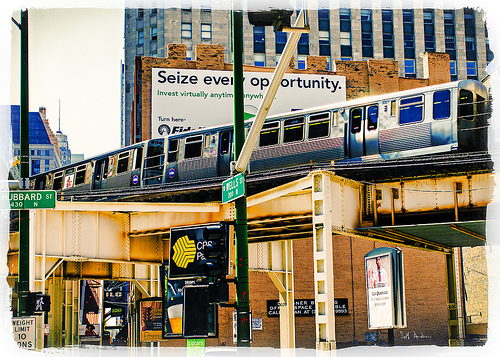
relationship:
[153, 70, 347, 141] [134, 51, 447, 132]
large sign on side of building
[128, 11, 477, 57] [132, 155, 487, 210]
offices are behind tracks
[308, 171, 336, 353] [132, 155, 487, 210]
support beams are under tracks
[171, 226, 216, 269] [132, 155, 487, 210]
sign under tracks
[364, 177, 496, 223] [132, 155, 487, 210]
large beams are under tracks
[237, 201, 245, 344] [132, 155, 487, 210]
green post next to tracks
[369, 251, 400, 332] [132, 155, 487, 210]
advertisment under tracks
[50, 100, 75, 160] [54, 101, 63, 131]
building has pole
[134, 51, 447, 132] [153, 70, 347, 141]
building has large sign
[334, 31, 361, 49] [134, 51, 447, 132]
windows are on building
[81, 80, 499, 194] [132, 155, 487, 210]
train on tracks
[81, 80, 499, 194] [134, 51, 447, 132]
train next to building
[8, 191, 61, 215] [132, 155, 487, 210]
street signs next to tracks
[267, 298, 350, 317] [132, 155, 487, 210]
black sign under tracks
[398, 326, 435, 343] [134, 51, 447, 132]
writting on building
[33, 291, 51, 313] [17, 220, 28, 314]
cross walk sign on pole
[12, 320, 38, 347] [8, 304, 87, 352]
weight limit sign in corner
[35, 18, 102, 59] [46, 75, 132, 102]
gray sky in back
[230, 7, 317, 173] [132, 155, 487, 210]
silver pole next to tracks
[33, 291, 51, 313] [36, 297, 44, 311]
cross walk sign with man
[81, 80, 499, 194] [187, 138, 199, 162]
train has windows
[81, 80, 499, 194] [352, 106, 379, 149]
train has doors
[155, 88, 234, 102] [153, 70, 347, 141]
green words on large sign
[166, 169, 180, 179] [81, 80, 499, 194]
blue circle on train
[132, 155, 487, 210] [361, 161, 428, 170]
tracks are made of steel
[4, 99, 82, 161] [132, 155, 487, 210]
buildings behind tracks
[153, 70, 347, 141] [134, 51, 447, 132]
large sign attached to building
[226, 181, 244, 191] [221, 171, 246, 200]
wells st on sign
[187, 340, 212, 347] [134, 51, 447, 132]
green sign on building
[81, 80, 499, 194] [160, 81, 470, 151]
train has cars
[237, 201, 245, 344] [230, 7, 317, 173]
green post attached to silver pole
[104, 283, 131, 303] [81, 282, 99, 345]
ads on street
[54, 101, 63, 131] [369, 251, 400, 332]
pole under advertisement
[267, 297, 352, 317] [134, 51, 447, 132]
black sign on building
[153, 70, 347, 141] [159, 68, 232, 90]
large sign has black letters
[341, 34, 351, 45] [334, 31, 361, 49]
curtians in windows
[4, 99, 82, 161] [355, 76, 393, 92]
buildings made out of bricks